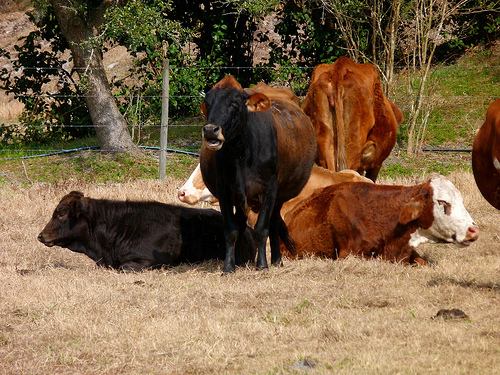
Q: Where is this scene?
A: A farm.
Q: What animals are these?
A: Cows.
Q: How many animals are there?
A: Six.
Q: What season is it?
A: Summer.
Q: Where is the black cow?
A: On the far left.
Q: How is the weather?
A: Sunny.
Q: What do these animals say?
A: Moo.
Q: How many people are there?
A: None.